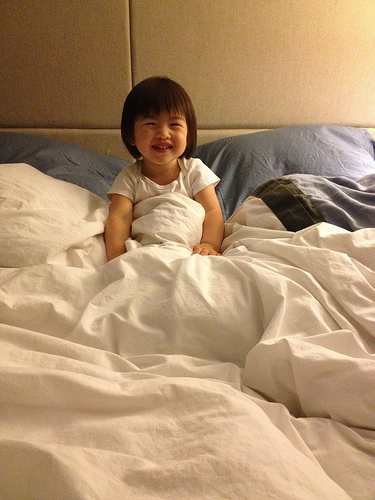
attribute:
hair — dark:
[121, 73, 198, 119]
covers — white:
[7, 168, 365, 422]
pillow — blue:
[194, 125, 374, 217]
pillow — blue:
[1, 129, 134, 200]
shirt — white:
[106, 155, 221, 199]